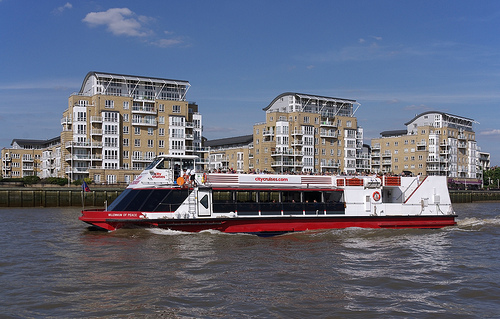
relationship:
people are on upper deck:
[217, 164, 247, 175] [197, 166, 420, 190]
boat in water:
[87, 154, 462, 233] [184, 245, 435, 300]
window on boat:
[128, 186, 180, 209] [83, 150, 465, 240]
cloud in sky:
[102, 13, 145, 35] [231, 29, 308, 66]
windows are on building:
[102, 110, 122, 171] [68, 74, 208, 172]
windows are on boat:
[236, 190, 319, 214] [78, 155, 458, 237]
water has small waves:
[144, 248, 425, 307] [357, 266, 417, 284]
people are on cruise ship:
[180, 160, 199, 181] [97, 147, 467, 231]